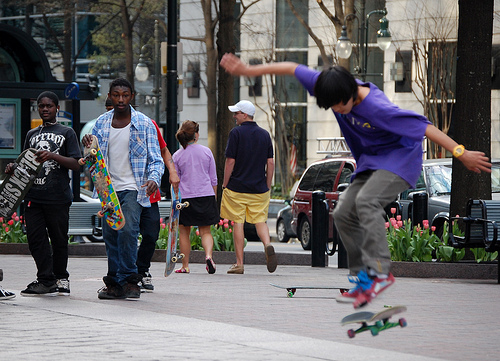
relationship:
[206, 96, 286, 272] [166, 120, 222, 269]
man walking with woman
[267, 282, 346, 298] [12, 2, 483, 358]
skate board in picture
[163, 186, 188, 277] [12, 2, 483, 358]
skating board in picture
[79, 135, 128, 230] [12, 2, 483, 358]
skate board in picture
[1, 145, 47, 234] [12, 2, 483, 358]
skateboard in picture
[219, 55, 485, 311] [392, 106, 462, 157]
boy has arm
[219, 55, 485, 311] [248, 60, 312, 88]
boy has arm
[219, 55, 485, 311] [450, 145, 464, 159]
boy wearing watch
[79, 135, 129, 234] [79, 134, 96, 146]
skate board in hand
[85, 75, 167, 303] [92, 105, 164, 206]
boy wearing plaid shirt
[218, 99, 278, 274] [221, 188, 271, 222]
man wearing yellow shorts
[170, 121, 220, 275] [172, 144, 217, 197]
girl wearing purple shirt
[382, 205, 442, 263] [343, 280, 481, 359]
flowers next to side walk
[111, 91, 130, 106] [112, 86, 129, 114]
admiring look on face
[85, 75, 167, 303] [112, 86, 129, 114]
boy has face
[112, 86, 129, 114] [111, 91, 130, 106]
face has admiring look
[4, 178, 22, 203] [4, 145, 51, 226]
stickers on skateboard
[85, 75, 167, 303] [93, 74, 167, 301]
boy behind dude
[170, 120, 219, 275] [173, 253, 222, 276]
girl wears shoes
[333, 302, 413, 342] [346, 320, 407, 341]
skateboard has wheels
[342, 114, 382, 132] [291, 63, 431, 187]
logo on tee shirt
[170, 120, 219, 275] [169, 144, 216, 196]
girl wears purple shirt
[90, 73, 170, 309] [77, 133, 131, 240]
boy wears skateboard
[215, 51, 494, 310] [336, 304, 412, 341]
boy does skateboard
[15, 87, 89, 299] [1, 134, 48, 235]
boy holds skateboard